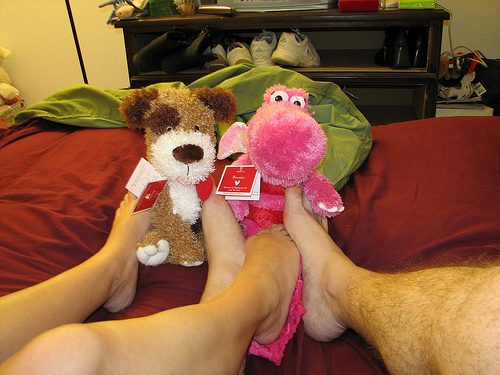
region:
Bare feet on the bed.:
[238, 189, 346, 344]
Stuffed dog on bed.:
[120, 79, 212, 268]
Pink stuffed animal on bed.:
[218, 83, 338, 270]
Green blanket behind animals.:
[42, 62, 371, 178]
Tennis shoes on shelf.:
[194, 43, 319, 74]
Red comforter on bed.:
[2, 118, 496, 373]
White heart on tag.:
[228, 177, 242, 189]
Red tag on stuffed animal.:
[215, 160, 260, 196]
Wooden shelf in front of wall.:
[110, 12, 436, 124]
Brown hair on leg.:
[336, 244, 498, 372]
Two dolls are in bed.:
[91, 85, 345, 291]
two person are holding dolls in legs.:
[91, 87, 387, 362]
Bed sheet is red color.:
[381, 133, 469, 253]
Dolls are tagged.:
[115, 156, 310, 240]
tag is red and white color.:
[214, 160, 277, 218]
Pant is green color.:
[64, 57, 356, 202]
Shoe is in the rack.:
[116, 0, 348, 75]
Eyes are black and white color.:
[263, 75, 320, 152]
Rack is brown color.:
[109, 4, 483, 109]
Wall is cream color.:
[10, 9, 117, 98]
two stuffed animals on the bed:
[129, 83, 372, 222]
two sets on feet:
[99, 170, 404, 313]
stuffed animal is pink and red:
[249, 124, 311, 208]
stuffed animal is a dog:
[147, 108, 197, 233]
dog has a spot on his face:
[141, 101, 199, 142]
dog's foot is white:
[135, 244, 183, 271]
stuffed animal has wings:
[223, 114, 260, 164]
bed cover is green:
[50, 98, 119, 144]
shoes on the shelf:
[247, 33, 320, 76]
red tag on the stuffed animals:
[224, 158, 277, 208]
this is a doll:
[243, 90, 340, 197]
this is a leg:
[73, 321, 229, 352]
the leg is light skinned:
[119, 345, 189, 372]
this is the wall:
[5, 13, 65, 72]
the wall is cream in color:
[31, 27, 70, 78]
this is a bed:
[376, 142, 494, 182]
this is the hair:
[366, 278, 471, 352]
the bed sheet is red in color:
[413, 142, 497, 214]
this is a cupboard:
[349, 63, 386, 85]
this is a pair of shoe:
[247, 34, 317, 66]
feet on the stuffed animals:
[87, 209, 361, 317]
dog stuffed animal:
[142, 94, 203, 227]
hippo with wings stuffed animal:
[237, 112, 295, 210]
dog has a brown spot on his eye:
[150, 100, 186, 145]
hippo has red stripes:
[256, 175, 292, 231]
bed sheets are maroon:
[4, 126, 60, 191]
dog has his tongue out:
[178, 169, 198, 190]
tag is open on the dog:
[120, 159, 162, 209]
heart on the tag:
[224, 169, 277, 203]